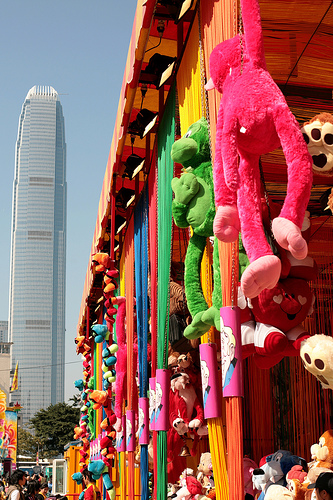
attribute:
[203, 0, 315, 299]
monkey — pink, stuffed, displayed, hanging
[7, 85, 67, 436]
building — tall, white, narrow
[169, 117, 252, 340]
monkey — green, displayed, toy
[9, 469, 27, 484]
hair — black, short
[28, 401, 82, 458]
tree — green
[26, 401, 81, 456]
leaves — green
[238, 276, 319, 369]
stuffed animal — heart-shaped, red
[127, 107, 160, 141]
light — black, on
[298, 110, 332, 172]
paw — white, large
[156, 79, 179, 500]
curtain — green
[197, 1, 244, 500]
curtain — peach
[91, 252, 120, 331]
snake — red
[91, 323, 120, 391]
snake — blue, green